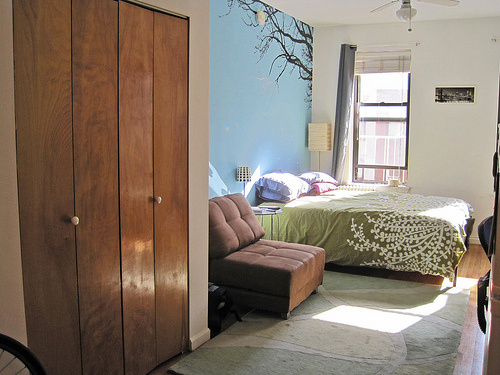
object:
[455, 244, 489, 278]
floor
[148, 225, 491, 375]
ground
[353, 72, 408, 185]
open window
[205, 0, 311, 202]
decal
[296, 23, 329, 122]
corner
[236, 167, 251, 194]
lamp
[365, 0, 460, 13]
ceiling fan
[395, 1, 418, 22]
lamp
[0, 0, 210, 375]
closet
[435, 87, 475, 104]
picture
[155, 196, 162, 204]
knob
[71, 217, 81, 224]
knob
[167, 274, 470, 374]
rug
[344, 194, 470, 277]
designed cover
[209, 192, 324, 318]
brown chair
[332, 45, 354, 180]
curtains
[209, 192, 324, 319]
love seat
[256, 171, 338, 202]
pillows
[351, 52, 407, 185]
window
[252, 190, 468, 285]
bed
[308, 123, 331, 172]
lamp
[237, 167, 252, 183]
lampshade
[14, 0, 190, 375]
closet door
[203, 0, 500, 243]
wall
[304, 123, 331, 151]
shade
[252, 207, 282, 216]
table